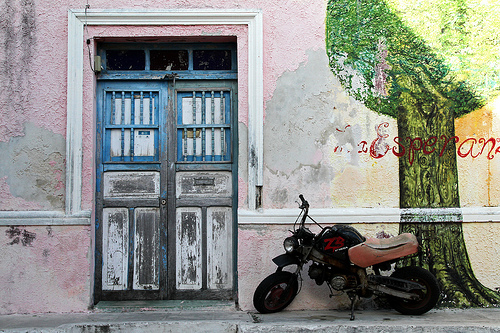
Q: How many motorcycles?
A: 1.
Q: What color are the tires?
A: Black.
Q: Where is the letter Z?
A: On the motorcycle.